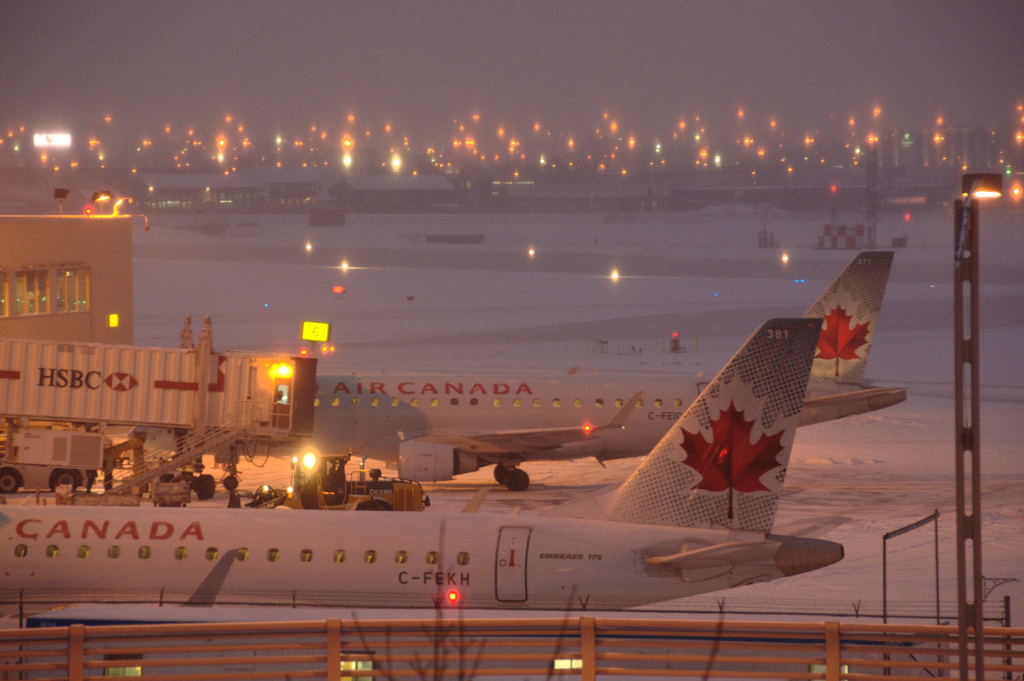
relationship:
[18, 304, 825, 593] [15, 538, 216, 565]
airplane on side windows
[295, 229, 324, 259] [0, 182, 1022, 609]
light on runway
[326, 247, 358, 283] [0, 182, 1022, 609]
light on runway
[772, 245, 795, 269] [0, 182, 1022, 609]
light on runway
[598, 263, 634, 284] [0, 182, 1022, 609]
light on runway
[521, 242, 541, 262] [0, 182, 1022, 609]
light on runway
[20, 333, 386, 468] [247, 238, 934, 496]
loading apparatus on airplane